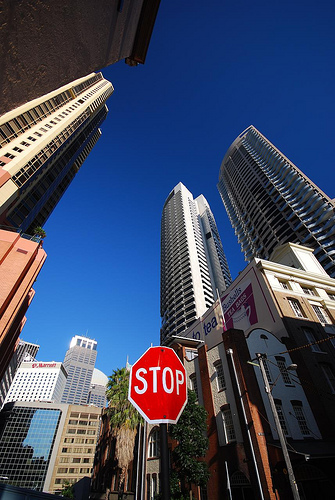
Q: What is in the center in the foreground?
A: Stop sign.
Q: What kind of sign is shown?
A: A stop sign.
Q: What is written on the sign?
A: Stop.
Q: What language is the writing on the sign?
A: English.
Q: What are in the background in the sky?
A: Sky scrapers.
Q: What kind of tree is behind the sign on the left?
A: Palm.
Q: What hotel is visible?
A: Marriott.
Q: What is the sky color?
A: Blue.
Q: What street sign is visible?
A: Stop.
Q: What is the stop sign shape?
A: Octagon.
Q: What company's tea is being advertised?
A: Bushells.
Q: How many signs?
A: 1.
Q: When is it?
A: Day time.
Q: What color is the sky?
A: Blue.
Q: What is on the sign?
A: Letters.